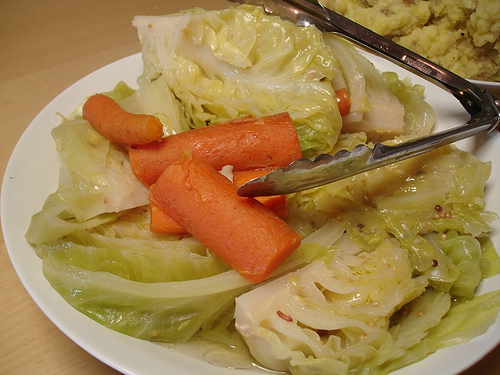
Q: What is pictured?
A: Cabbage.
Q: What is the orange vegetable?
A: Carrots.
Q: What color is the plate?
A: White.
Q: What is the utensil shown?
A: Tongs.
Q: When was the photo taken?
A: Dinner.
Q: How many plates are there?
A: One.